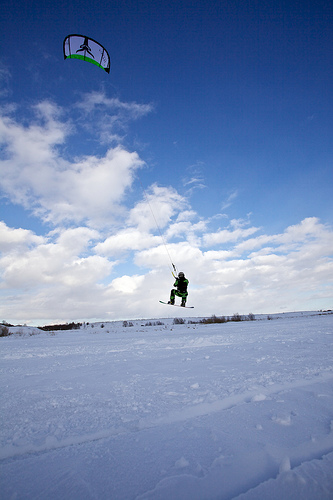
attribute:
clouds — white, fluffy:
[4, 90, 331, 315]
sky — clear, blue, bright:
[2, 2, 333, 321]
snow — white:
[6, 327, 332, 493]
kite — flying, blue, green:
[47, 26, 117, 77]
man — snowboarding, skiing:
[162, 264, 197, 304]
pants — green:
[164, 288, 194, 308]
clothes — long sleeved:
[162, 278, 201, 305]